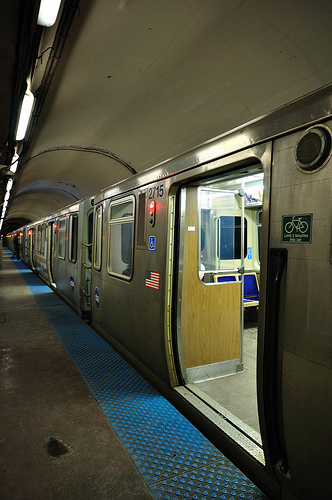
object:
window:
[58, 220, 66, 260]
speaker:
[292, 122, 332, 174]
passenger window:
[106, 196, 137, 279]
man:
[11, 232, 22, 261]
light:
[149, 202, 154, 210]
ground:
[12, 362, 84, 450]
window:
[217, 215, 247, 258]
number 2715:
[148, 184, 164, 199]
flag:
[145, 270, 159, 292]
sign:
[148, 235, 156, 251]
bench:
[145, 270, 160, 291]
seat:
[213, 273, 260, 309]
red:
[149, 203, 162, 211]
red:
[53, 224, 57, 230]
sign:
[280, 213, 312, 243]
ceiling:
[0, 0, 331, 237]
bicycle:
[285, 216, 309, 234]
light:
[53, 223, 59, 230]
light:
[27, 230, 31, 236]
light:
[20, 232, 24, 237]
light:
[14, 233, 18, 237]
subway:
[1, 0, 331, 497]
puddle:
[44, 436, 72, 461]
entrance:
[167, 154, 277, 465]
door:
[163, 154, 266, 470]